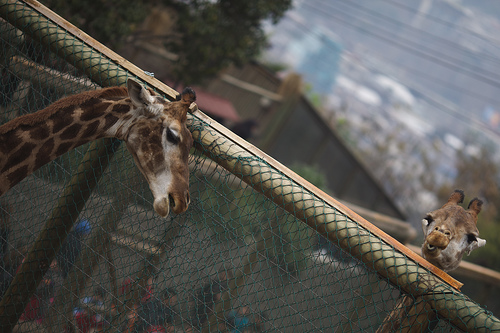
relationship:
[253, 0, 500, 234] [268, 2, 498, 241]
clouds in sky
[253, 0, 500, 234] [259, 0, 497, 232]
clouds in blue sky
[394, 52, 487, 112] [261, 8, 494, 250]
clouds in sky